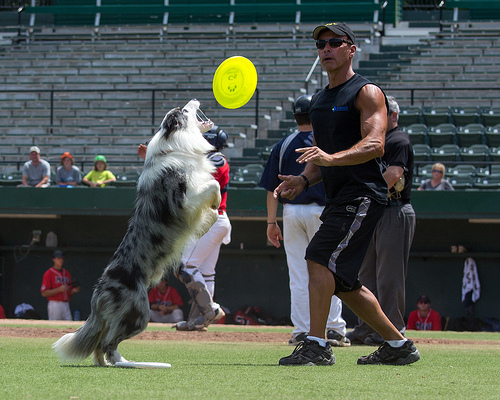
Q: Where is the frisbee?
A: In the air.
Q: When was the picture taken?
A: Daytime.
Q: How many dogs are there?
A: One.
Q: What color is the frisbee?
A: Yellow.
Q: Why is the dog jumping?
A: To catch the frisbee.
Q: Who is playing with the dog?
A: The man.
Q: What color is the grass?
A: Green.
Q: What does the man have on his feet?
A: Tennis shoes.